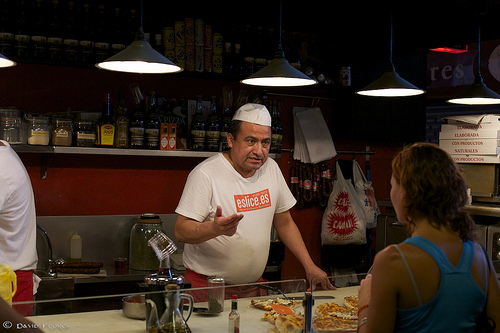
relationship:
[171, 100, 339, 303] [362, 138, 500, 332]
cook talks to lady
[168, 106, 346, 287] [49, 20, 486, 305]
cook works in restaurant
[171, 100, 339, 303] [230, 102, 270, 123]
cook wearing hat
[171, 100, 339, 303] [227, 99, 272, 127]
cook wearing hat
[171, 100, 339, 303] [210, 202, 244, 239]
cook with hand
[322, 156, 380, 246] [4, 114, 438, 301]
bags near wall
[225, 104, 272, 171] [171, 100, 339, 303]
head of cook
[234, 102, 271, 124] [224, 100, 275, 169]
hat on head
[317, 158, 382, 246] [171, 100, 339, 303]
bags behind cook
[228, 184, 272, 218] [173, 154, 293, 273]
word on shirt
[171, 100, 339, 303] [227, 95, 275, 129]
cook wearing hat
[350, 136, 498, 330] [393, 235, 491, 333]
lady wearing blue tank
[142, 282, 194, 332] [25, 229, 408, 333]
bottle on table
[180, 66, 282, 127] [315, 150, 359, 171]
wall hanging off hook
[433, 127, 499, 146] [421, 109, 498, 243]
boxes on shelf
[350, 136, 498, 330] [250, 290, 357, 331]
lady ordering pizza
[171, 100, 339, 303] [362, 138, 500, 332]
cook talking lady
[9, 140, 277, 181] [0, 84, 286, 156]
shelf holding spices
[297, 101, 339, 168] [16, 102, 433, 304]
sheet on wall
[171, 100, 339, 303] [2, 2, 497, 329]
cook working in restaurant